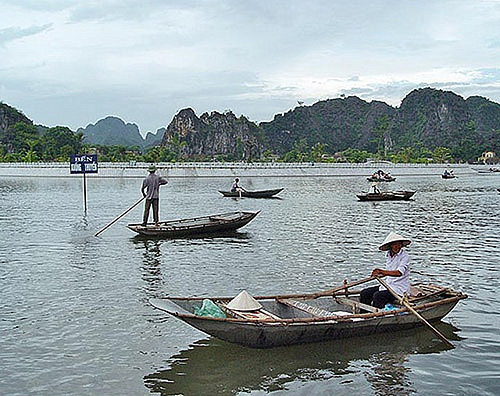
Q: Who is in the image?
A: People with boats.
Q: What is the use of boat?
A: Travelling.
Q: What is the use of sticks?
A: To travel further.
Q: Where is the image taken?
A: In river.